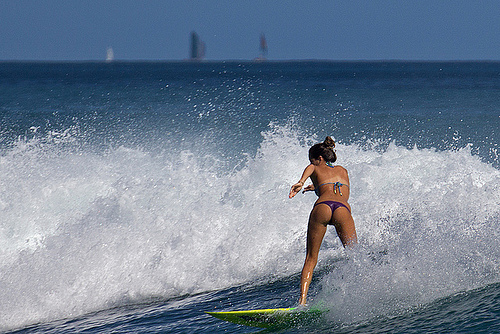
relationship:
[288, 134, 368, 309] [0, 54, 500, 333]
woman in ocean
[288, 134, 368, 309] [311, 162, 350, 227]
woman in bikini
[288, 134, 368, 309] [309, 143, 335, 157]
woman has hair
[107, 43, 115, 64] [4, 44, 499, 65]
sail boat in background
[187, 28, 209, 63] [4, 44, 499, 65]
sail boat in background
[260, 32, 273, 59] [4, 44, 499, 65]
sail boat in background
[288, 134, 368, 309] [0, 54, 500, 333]
surfer in ocean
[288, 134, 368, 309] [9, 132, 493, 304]
surfer catching wave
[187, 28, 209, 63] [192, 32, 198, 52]
boat with sail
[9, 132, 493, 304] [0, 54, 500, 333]
wave in water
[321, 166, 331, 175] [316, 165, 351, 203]
tan on back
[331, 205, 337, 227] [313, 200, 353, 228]
wedgie in butt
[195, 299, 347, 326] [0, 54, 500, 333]
surfboard in water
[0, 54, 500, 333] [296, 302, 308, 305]
water on foot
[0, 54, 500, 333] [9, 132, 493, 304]
water in waves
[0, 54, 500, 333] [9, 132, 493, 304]
ocean has waves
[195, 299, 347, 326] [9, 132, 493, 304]
surfboard on waves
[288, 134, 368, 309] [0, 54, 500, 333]
girl in ocean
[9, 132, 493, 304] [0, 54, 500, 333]
waves on ocean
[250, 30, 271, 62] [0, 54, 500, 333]
sail boat in water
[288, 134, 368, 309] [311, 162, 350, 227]
girl wearing bikini